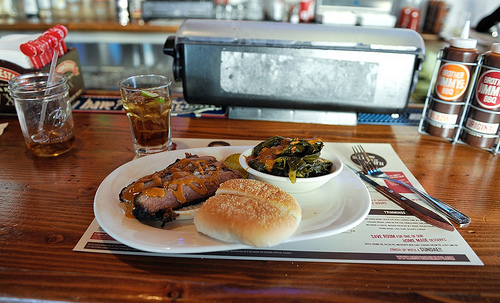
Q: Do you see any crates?
A: No, there are no crates.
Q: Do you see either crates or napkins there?
A: No, there are no crates or napkins.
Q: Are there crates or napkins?
A: No, there are no crates or napkins.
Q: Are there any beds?
A: No, there are no beds.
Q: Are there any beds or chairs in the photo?
A: No, there are no beds or chairs.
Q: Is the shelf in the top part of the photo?
A: Yes, the shelf is in the top of the image.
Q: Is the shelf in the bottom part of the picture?
A: No, the shelf is in the top of the image.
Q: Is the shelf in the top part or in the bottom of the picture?
A: The shelf is in the top of the image.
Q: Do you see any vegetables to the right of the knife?
A: No, the vegetable is to the left of the knife.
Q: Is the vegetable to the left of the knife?
A: Yes, the vegetable is to the left of the knife.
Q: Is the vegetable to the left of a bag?
A: No, the vegetable is to the left of the knife.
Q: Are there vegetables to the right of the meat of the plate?
A: Yes, there is a vegetable to the right of the meat.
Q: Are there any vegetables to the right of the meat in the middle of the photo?
A: Yes, there is a vegetable to the right of the meat.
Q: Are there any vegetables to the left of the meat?
A: No, the vegetable is to the right of the meat.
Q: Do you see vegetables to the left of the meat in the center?
A: No, the vegetable is to the right of the meat.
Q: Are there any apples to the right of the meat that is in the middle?
A: No, there is a vegetable to the right of the meat.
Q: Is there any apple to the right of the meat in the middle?
A: No, there is a vegetable to the right of the meat.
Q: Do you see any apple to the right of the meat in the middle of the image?
A: No, there is a vegetable to the right of the meat.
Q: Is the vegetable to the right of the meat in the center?
A: Yes, the vegetable is to the right of the meat.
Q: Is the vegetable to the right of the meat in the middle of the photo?
A: Yes, the vegetable is to the right of the meat.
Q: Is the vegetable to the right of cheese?
A: No, the vegetable is to the right of the meat.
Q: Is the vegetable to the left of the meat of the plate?
A: No, the vegetable is to the right of the meat.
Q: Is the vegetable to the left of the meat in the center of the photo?
A: No, the vegetable is to the right of the meat.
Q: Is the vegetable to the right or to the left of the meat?
A: The vegetable is to the right of the meat.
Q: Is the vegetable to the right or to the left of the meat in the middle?
A: The vegetable is to the right of the meat.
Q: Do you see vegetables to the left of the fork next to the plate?
A: Yes, there is a vegetable to the left of the fork.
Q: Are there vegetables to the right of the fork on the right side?
A: No, the vegetable is to the left of the fork.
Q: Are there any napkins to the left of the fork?
A: No, there is a vegetable to the left of the fork.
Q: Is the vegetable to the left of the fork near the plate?
A: Yes, the vegetable is to the left of the fork.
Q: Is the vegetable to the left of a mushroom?
A: No, the vegetable is to the left of the fork.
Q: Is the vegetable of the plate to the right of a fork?
A: No, the vegetable is to the left of a fork.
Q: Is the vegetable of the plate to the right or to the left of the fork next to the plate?
A: The vegetable is to the left of the fork.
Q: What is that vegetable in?
A: The vegetable is in the bowl.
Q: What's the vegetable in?
A: The vegetable is in the bowl.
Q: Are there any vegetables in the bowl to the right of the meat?
A: Yes, there is a vegetable in the bowl.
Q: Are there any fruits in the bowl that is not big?
A: No, there is a vegetable in the bowl.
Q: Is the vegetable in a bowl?
A: Yes, the vegetable is in a bowl.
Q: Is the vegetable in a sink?
A: No, the vegetable is in a bowl.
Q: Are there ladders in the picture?
A: No, there are no ladders.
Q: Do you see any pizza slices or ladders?
A: No, there are no ladders or pizza slices.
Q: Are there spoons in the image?
A: Yes, there is a spoon.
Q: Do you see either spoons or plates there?
A: Yes, there is a spoon.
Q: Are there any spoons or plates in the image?
A: Yes, there is a spoon.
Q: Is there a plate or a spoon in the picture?
A: Yes, there is a spoon.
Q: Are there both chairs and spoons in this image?
A: No, there is a spoon but no chairs.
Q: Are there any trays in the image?
A: No, there are no trays.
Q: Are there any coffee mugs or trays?
A: No, there are no trays or coffee mugs.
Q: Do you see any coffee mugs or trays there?
A: No, there are no trays or coffee mugs.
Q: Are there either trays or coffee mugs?
A: No, there are no trays or coffee mugs.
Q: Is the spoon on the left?
A: Yes, the spoon is on the left of the image.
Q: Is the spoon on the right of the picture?
A: No, the spoon is on the left of the image.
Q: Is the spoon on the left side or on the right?
A: The spoon is on the left of the image.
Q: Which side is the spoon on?
A: The spoon is on the left of the image.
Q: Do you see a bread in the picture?
A: Yes, there is a bread.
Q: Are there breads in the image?
A: Yes, there is a bread.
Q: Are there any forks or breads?
A: Yes, there is a bread.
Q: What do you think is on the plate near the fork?
A: The bread is on the plate.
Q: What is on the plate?
A: The bread is on the plate.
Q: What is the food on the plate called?
A: The food is a bread.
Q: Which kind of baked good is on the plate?
A: The food is a bread.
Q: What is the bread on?
A: The bread is on the plate.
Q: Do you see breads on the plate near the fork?
A: Yes, there is a bread on the plate.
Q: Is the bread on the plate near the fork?
A: Yes, the bread is on the plate.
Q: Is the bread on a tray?
A: No, the bread is on the plate.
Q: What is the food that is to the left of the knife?
A: The food is a bread.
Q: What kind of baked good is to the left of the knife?
A: The food is a bread.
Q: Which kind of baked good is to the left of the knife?
A: The food is a bread.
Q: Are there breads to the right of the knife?
A: No, the bread is to the left of the knife.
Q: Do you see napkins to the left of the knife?
A: No, there is a bread to the left of the knife.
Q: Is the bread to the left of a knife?
A: Yes, the bread is to the left of a knife.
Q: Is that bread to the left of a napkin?
A: No, the bread is to the left of a knife.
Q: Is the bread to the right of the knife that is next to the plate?
A: No, the bread is to the left of the knife.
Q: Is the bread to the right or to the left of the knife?
A: The bread is to the left of the knife.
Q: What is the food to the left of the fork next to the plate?
A: The food is a bread.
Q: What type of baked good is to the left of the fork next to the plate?
A: The food is a bread.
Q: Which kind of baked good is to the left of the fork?
A: The food is a bread.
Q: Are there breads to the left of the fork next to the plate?
A: Yes, there is a bread to the left of the fork.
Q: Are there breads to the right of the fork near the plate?
A: No, the bread is to the left of the fork.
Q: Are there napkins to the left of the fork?
A: No, there is a bread to the left of the fork.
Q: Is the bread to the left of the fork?
A: Yes, the bread is to the left of the fork.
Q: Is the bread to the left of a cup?
A: No, the bread is to the left of the fork.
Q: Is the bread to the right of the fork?
A: No, the bread is to the left of the fork.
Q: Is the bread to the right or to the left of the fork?
A: The bread is to the left of the fork.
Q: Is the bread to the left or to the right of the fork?
A: The bread is to the left of the fork.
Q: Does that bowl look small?
A: Yes, the bowl is small.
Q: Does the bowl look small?
A: Yes, the bowl is small.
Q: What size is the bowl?
A: The bowl is small.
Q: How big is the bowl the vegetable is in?
A: The bowl is small.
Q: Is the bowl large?
A: No, the bowl is small.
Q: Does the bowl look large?
A: No, the bowl is small.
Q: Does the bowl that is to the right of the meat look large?
A: No, the bowl is small.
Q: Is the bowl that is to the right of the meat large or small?
A: The bowl is small.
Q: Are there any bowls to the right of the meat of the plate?
A: Yes, there is a bowl to the right of the meat.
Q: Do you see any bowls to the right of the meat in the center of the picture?
A: Yes, there is a bowl to the right of the meat.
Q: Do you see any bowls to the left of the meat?
A: No, the bowl is to the right of the meat.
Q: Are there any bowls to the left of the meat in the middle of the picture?
A: No, the bowl is to the right of the meat.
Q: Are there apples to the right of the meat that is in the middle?
A: No, there is a bowl to the right of the meat.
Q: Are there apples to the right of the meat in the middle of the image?
A: No, there is a bowl to the right of the meat.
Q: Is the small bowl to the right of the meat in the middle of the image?
A: Yes, the bowl is to the right of the meat.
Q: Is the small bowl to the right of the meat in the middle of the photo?
A: Yes, the bowl is to the right of the meat.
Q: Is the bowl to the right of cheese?
A: No, the bowl is to the right of the meat.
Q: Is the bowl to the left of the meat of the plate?
A: No, the bowl is to the right of the meat.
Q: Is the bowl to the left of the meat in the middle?
A: No, the bowl is to the right of the meat.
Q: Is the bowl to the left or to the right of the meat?
A: The bowl is to the right of the meat.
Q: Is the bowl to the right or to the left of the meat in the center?
A: The bowl is to the right of the meat.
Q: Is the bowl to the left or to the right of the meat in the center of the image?
A: The bowl is to the right of the meat.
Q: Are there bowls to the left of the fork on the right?
A: Yes, there is a bowl to the left of the fork.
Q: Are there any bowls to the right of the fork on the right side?
A: No, the bowl is to the left of the fork.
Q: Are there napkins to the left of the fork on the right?
A: No, there is a bowl to the left of the fork.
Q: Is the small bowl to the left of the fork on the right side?
A: Yes, the bowl is to the left of the fork.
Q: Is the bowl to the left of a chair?
A: No, the bowl is to the left of the fork.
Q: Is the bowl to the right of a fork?
A: No, the bowl is to the left of a fork.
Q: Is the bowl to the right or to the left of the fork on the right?
A: The bowl is to the left of the fork.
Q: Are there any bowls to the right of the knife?
A: No, the bowl is to the left of the knife.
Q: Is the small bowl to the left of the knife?
A: Yes, the bowl is to the left of the knife.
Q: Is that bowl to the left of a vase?
A: No, the bowl is to the left of the knife.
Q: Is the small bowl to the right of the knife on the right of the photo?
A: No, the bowl is to the left of the knife.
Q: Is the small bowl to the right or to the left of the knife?
A: The bowl is to the left of the knife.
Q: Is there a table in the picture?
A: Yes, there is a table.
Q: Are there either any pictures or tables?
A: Yes, there is a table.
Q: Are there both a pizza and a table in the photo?
A: No, there is a table but no pizzas.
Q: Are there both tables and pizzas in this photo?
A: No, there is a table but no pizzas.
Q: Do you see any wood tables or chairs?
A: Yes, there is a wood table.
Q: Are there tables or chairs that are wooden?
A: Yes, the table is wooden.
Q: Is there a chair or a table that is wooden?
A: Yes, the table is wooden.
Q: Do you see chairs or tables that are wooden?
A: Yes, the table is wooden.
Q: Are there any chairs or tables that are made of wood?
A: Yes, the table is made of wood.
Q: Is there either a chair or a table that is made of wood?
A: Yes, the table is made of wood.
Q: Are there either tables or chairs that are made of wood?
A: Yes, the table is made of wood.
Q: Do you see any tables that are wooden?
A: Yes, there is a wood table.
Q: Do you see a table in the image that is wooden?
A: Yes, there is a table that is wooden.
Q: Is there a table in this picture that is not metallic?
A: Yes, there is a wooden table.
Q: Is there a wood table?
A: Yes, there is a table that is made of wood.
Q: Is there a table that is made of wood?
A: Yes, there is a table that is made of wood.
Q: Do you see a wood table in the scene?
A: Yes, there is a table that is made of wood.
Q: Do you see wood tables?
A: Yes, there is a table that is made of wood.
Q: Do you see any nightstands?
A: No, there are no nightstands.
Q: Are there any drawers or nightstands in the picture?
A: No, there are no nightstands or drawers.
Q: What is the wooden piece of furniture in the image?
A: The piece of furniture is a table.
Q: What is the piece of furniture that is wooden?
A: The piece of furniture is a table.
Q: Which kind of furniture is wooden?
A: The furniture is a table.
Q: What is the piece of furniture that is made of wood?
A: The piece of furniture is a table.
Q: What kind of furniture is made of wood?
A: The furniture is a table.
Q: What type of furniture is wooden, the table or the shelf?
A: The table is wooden.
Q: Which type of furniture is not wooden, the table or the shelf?
A: The shelf is not wooden.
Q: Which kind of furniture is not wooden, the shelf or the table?
A: The shelf is not wooden.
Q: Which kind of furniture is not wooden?
A: The furniture is a shelf.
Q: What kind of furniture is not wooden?
A: The furniture is a shelf.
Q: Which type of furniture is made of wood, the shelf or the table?
A: The table is made of wood.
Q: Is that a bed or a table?
A: That is a table.